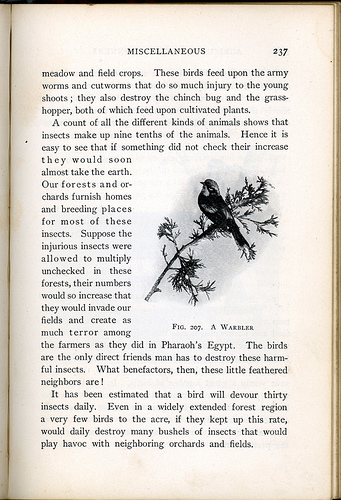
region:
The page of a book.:
[20, 4, 306, 486]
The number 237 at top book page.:
[270, 44, 292, 60]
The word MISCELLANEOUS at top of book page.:
[123, 39, 211, 59]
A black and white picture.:
[153, 162, 294, 320]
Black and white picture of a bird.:
[191, 171, 257, 256]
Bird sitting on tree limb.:
[143, 160, 280, 307]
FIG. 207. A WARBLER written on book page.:
[167, 322, 258, 333]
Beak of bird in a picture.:
[197, 175, 205, 186]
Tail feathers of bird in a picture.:
[230, 221, 248, 246]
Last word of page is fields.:
[227, 438, 252, 450]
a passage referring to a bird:
[27, 53, 281, 166]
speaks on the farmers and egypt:
[42, 336, 284, 385]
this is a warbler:
[182, 175, 267, 272]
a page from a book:
[21, 39, 303, 496]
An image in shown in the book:
[145, 175, 279, 301]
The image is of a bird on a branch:
[136, 160, 282, 309]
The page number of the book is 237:
[268, 44, 286, 55]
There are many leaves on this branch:
[140, 170, 277, 300]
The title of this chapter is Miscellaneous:
[125, 44, 201, 51]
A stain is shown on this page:
[314, 5, 332, 62]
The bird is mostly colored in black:
[196, 178, 252, 249]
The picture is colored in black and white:
[146, 174, 277, 300]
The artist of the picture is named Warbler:
[170, 322, 253, 329]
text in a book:
[40, 384, 61, 397]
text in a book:
[66, 388, 77, 400]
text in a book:
[81, 386, 102, 403]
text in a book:
[98, 387, 150, 405]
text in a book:
[184, 382, 210, 405]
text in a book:
[225, 382, 257, 402]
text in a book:
[166, 439, 204, 451]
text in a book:
[109, 436, 169, 453]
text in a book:
[41, 301, 131, 318]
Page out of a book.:
[143, 468, 159, 499]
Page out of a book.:
[220, 463, 229, 492]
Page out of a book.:
[207, 430, 245, 440]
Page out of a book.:
[141, 404, 150, 441]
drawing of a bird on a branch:
[142, 174, 280, 303]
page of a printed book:
[9, 3, 336, 498]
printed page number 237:
[270, 46, 288, 58]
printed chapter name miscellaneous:
[126, 47, 205, 56]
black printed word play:
[40, 438, 57, 448]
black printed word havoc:
[61, 436, 86, 448]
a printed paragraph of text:
[38, 387, 288, 449]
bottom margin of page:
[9, 449, 328, 498]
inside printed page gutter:
[11, 6, 41, 498]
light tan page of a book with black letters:
[9, 4, 331, 497]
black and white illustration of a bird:
[197, 177, 252, 260]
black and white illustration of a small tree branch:
[143, 175, 281, 307]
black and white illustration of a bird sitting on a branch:
[142, 173, 280, 301]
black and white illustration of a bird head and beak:
[197, 177, 218, 194]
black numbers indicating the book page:
[271, 47, 289, 56]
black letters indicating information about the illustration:
[171, 322, 255, 331]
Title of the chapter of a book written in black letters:
[126, 45, 204, 55]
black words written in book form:
[37, 68, 292, 449]